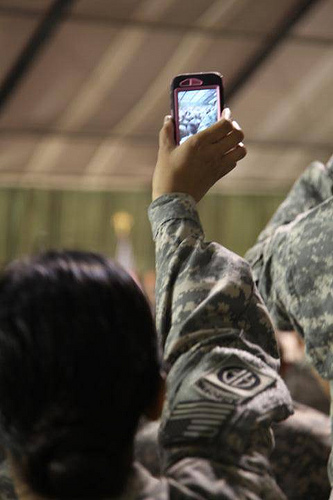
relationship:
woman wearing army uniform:
[3, 107, 294, 499] [1, 190, 294, 499]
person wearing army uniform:
[133, 155, 332, 499] [131, 155, 331, 499]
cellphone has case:
[170, 72, 223, 147] [172, 70, 225, 148]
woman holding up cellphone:
[3, 107, 294, 499] [170, 72, 223, 147]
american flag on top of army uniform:
[160, 401, 238, 445] [1, 190, 294, 499]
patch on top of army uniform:
[192, 352, 278, 406] [1, 190, 294, 499]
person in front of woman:
[133, 155, 332, 499] [3, 107, 294, 499]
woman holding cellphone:
[3, 107, 294, 499] [170, 72, 223, 147]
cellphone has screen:
[170, 72, 223, 147] [178, 89, 218, 138]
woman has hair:
[3, 107, 294, 499] [0, 250, 162, 498]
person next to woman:
[133, 155, 332, 499] [3, 107, 294, 499]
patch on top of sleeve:
[192, 352, 278, 406] [148, 192, 294, 499]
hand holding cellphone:
[152, 108, 248, 198] [170, 72, 223, 147]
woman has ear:
[3, 107, 294, 499] [145, 373, 166, 422]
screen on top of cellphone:
[178, 89, 218, 138] [170, 72, 223, 147]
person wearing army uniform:
[133, 155, 332, 499] [1, 190, 294, 499]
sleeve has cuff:
[148, 192, 294, 499] [144, 191, 205, 239]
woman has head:
[3, 107, 294, 499] [4, 246, 167, 445]